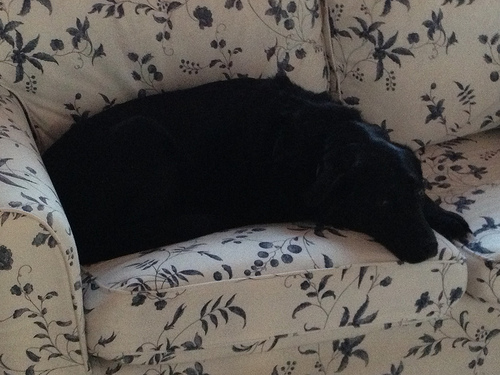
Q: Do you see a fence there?
A: No, there are no fences.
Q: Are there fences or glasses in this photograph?
A: No, there are no fences or glasses.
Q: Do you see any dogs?
A: Yes, there is a dog.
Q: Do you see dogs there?
A: Yes, there is a dog.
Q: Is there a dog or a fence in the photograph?
A: Yes, there is a dog.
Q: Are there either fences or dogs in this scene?
A: Yes, there is a dog.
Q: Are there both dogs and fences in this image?
A: No, there is a dog but no fences.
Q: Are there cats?
A: No, there are no cats.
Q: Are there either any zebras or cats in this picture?
A: No, there are no cats or zebras.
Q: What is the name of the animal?
A: The animal is a dog.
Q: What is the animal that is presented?
A: The animal is a dog.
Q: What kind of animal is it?
A: The animal is a dog.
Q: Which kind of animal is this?
A: This is a dog.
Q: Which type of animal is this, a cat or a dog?
A: This is a dog.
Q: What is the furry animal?
A: The animal is a dog.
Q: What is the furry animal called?
A: The animal is a dog.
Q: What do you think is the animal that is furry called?
A: The animal is a dog.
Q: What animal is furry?
A: The animal is a dog.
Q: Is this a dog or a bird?
A: This is a dog.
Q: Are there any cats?
A: No, there are no cats.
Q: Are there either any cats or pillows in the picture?
A: No, there are no cats or pillows.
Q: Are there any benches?
A: No, there are no benches.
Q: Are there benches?
A: No, there are no benches.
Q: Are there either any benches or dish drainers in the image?
A: No, there are no benches or dish drainers.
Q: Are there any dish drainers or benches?
A: No, there are no benches or dish drainers.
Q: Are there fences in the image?
A: No, there are no fences.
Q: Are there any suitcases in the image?
A: No, there are no suitcases.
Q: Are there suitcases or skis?
A: No, there are no suitcases or skis.